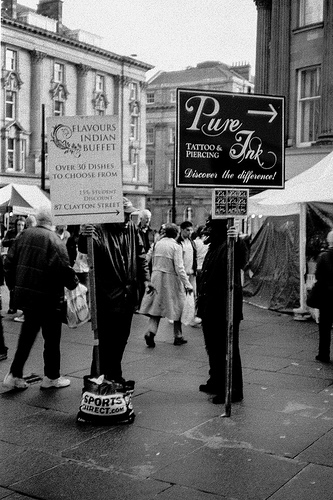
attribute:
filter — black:
[15, 18, 330, 409]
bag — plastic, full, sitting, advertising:
[70, 375, 175, 445]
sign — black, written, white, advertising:
[162, 80, 271, 175]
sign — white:
[40, 100, 123, 208]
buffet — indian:
[262, 225, 328, 302]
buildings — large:
[21, 14, 230, 105]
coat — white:
[159, 243, 196, 333]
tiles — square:
[76, 431, 206, 464]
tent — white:
[286, 148, 330, 257]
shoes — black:
[193, 372, 257, 422]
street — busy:
[72, 220, 328, 369]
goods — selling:
[217, 214, 318, 279]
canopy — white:
[280, 142, 326, 222]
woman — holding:
[17, 225, 100, 351]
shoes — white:
[0, 368, 70, 401]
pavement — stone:
[170, 370, 298, 487]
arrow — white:
[220, 97, 308, 138]